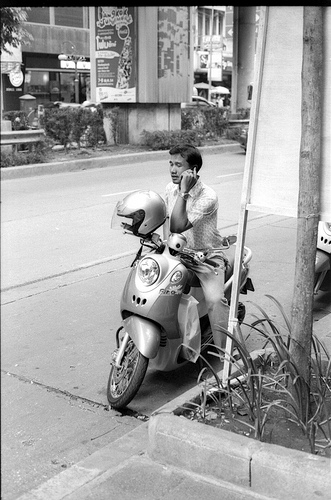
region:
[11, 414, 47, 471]
Small markings on the pavement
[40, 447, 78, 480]
Small markings on the pavement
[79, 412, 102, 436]
Small markings on the pavement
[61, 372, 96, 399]
Small markings on the pavement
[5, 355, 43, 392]
Small markings on the pavement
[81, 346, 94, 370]
Small markings on the pavement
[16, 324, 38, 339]
Small markings on the pavement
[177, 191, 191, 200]
a man's wristwatch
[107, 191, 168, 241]
a silver motorcycle helmet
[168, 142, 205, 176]
a man's short cut black hair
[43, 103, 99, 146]
a small bush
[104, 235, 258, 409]
a small motorbike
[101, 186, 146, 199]
a white street marking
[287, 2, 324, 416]
part of a long tree branch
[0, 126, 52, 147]
part of a guard rail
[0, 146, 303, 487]
part of a roadway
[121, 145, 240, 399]
a guy sitting on a scooter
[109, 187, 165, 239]
a silver and black scooter helmet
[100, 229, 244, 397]
a silver motor scooter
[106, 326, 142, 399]
the front wheel of a scooter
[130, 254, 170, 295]
the headlight of a scooter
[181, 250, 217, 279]
the handle of a scooter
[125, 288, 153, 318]
the vent of a scooter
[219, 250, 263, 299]
the backseat of a scooter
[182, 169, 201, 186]
a guy holding a phone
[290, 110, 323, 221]
a skinny little tree stump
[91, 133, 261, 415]
person sitting on motorcycle with cell phone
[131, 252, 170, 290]
headlight on front of motorcycle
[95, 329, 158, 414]
front black tire on front of motorcycle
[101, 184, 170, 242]
metal helmet on front of motorcycle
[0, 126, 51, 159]
metal fence barrier on side of street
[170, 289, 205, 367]
bag on motorcycle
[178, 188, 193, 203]
watch on wrist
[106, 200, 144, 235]
glass shield on front of motorcycle helmet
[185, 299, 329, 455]
plants on side of street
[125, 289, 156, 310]
three black holes on front of motorcycle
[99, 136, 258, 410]
A man on a scooter talking on his cell phone